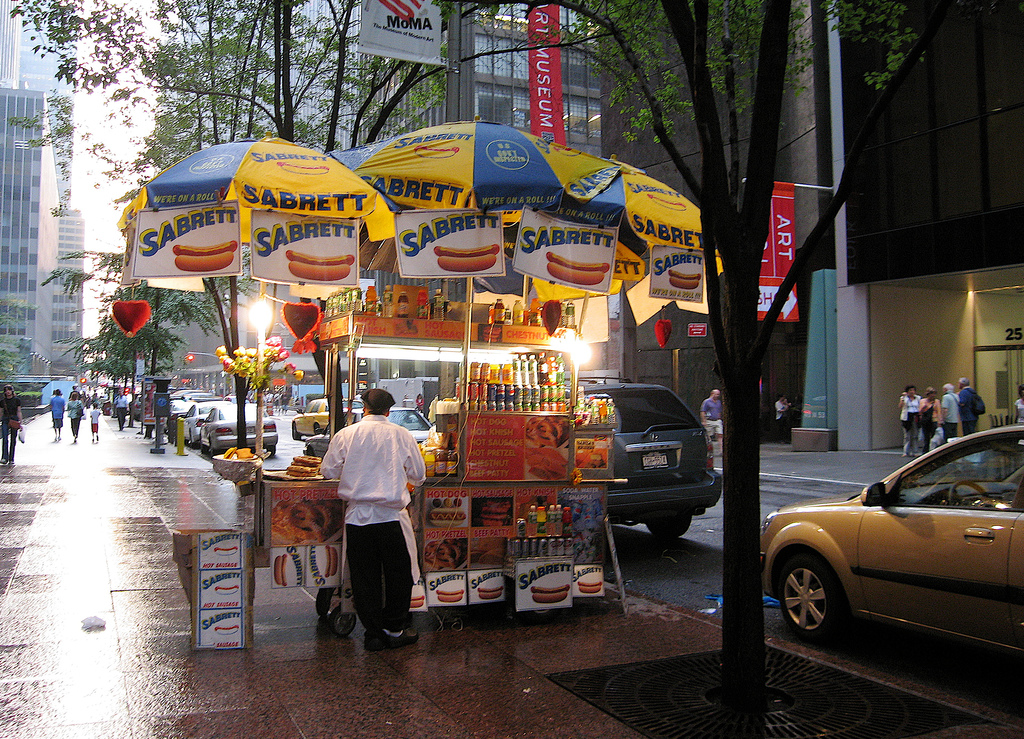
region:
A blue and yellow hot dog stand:
[123, 116, 776, 658]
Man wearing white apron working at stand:
[279, 377, 453, 669]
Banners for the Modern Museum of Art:
[525, 1, 826, 324]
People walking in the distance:
[18, 364, 180, 488]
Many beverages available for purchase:
[459, 330, 580, 422]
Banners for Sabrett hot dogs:
[132, 210, 709, 335]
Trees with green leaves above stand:
[38, 2, 844, 249]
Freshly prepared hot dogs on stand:
[268, 441, 314, 514]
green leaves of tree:
[539, 3, 951, 146]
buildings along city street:
[3, 2, 1022, 471]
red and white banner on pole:
[746, 177, 830, 320]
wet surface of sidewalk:
[1, 406, 995, 736]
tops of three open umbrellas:
[127, 121, 713, 233]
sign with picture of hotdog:
[250, 213, 362, 287]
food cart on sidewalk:
[174, 302, 623, 651]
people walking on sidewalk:
[0, 379, 144, 459]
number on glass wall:
[967, 286, 1021, 427]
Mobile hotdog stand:
[136, 123, 719, 686]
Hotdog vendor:
[315, 376, 421, 667]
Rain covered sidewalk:
[4, 379, 1008, 722]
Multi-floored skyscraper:
[0, 58, 117, 469]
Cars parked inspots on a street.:
[98, 359, 1019, 718]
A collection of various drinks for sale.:
[316, 287, 633, 478]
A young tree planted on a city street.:
[448, 56, 1005, 727]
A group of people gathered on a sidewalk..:
[870, 346, 1022, 490]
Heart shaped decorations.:
[70, 252, 706, 379]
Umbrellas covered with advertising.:
[119, 112, 746, 281]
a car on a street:
[751, 392, 1020, 686]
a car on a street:
[545, 358, 726, 559]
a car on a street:
[289, 385, 378, 444]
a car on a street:
[188, 392, 287, 457]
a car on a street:
[167, 398, 216, 437]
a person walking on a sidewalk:
[39, 388, 68, 427]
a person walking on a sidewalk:
[9, 379, 26, 472]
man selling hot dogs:
[124, 110, 707, 657]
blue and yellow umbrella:
[119, 126, 398, 466]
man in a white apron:
[324, 380, 435, 653]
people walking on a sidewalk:
[0, 370, 143, 470]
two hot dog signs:
[125, 195, 366, 294]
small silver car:
[760, 407, 1021, 682]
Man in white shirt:
[283, 379, 479, 675]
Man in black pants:
[315, 379, 429, 656]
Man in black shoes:
[313, 376, 460, 661]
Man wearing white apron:
[322, 391, 449, 639]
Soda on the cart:
[461, 354, 573, 408]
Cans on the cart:
[454, 351, 581, 402]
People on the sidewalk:
[34, 373, 117, 441]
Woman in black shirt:
[0, 380, 30, 464]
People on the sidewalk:
[875, 366, 983, 449]